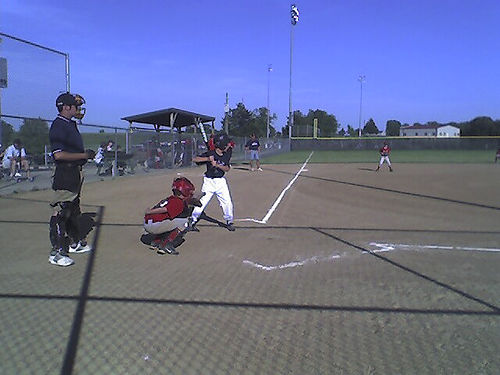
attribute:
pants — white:
[192, 177, 234, 224]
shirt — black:
[197, 150, 230, 178]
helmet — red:
[173, 177, 193, 203]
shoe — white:
[49, 250, 74, 267]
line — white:
[262, 150, 315, 224]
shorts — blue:
[249, 150, 258, 162]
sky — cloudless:
[1, 2, 500, 132]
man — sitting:
[3, 138, 33, 182]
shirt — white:
[2, 146, 27, 165]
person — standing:
[244, 133, 261, 171]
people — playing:
[143, 117, 500, 256]